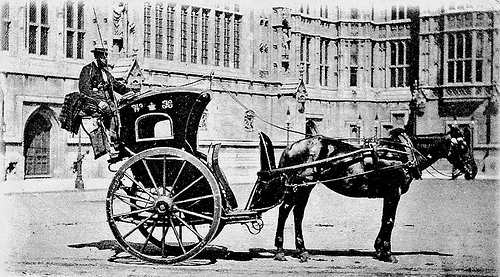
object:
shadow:
[66, 239, 454, 267]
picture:
[0, 0, 500, 277]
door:
[23, 111, 51, 179]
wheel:
[104, 146, 224, 263]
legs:
[276, 203, 293, 252]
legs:
[373, 192, 399, 255]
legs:
[292, 199, 307, 251]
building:
[0, 0, 499, 194]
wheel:
[129, 149, 227, 253]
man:
[79, 48, 142, 141]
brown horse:
[273, 123, 478, 262]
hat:
[90, 48, 109, 56]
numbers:
[161, 100, 173, 109]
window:
[135, 113, 174, 142]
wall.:
[3, 56, 278, 182]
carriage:
[59, 70, 477, 264]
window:
[25, 2, 48, 54]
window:
[66, 0, 84, 61]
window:
[144, 1, 151, 58]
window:
[213, 12, 220, 67]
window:
[234, 14, 241, 68]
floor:
[0, 177, 497, 277]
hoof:
[380, 253, 399, 263]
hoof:
[299, 251, 310, 262]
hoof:
[274, 252, 288, 261]